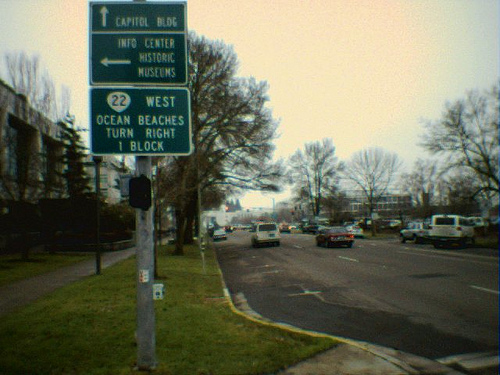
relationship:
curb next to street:
[233, 299, 297, 344] [205, 226, 497, 370]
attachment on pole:
[148, 279, 166, 304] [125, 154, 167, 368]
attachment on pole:
[136, 266, 151, 284] [125, 154, 167, 368]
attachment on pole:
[125, 170, 155, 212] [125, 154, 167, 368]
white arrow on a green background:
[98, 52, 134, 69] [91, 35, 180, 82]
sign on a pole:
[89, 2, 192, 155] [133, 155, 155, 371]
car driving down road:
[315, 229, 354, 248] [223, 221, 498, 361]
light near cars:
[225, 206, 230, 212] [208, 213, 469, 249]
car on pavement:
[311, 224, 352, 249] [221, 239, 498, 367]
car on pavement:
[245, 219, 286, 250] [221, 239, 498, 367]